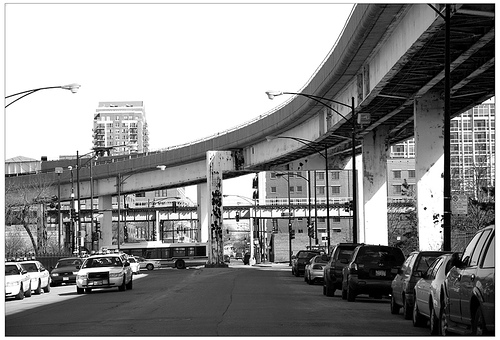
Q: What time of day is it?
A: Day time.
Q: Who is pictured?
A: No one.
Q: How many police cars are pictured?
A: One.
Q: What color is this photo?
A: Black and white.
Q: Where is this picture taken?
A: Underpass.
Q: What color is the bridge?
A: White.